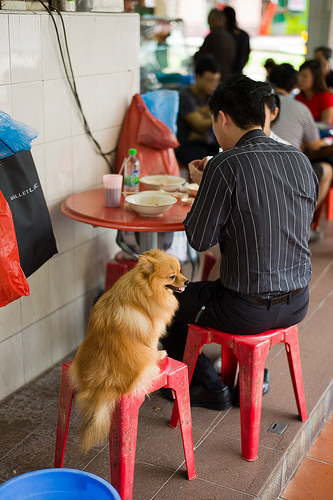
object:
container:
[0, 467, 120, 499]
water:
[6, 487, 112, 498]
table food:
[102, 148, 199, 217]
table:
[60, 186, 199, 232]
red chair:
[54, 348, 198, 499]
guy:
[159, 74, 320, 411]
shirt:
[183, 129, 319, 298]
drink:
[104, 187, 121, 207]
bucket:
[0, 467, 120, 500]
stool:
[167, 323, 309, 461]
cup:
[103, 174, 124, 208]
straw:
[118, 157, 127, 176]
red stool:
[167, 323, 309, 462]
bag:
[0, 192, 30, 308]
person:
[174, 55, 221, 167]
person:
[267, 62, 333, 243]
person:
[294, 59, 333, 125]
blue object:
[0, 467, 120, 499]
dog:
[65, 248, 190, 457]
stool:
[53, 350, 197, 500]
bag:
[0, 137, 59, 279]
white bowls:
[124, 193, 177, 218]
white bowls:
[139, 174, 186, 192]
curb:
[246, 416, 288, 490]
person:
[221, 6, 250, 73]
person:
[181, 8, 236, 83]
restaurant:
[0, 0, 333, 499]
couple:
[158, 73, 320, 411]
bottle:
[123, 148, 140, 198]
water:
[125, 164, 139, 196]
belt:
[234, 287, 305, 303]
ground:
[0, 222, 333, 500]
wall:
[0, 10, 140, 403]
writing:
[9, 183, 38, 202]